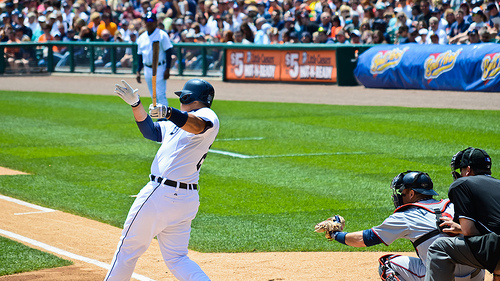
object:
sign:
[280, 50, 338, 83]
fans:
[346, 30, 361, 47]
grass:
[0, 90, 499, 252]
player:
[103, 79, 219, 175]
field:
[0, 69, 499, 280]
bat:
[143, 39, 162, 112]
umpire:
[419, 145, 500, 281]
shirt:
[147, 110, 219, 187]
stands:
[2, 2, 480, 80]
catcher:
[313, 169, 482, 280]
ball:
[313, 213, 347, 235]